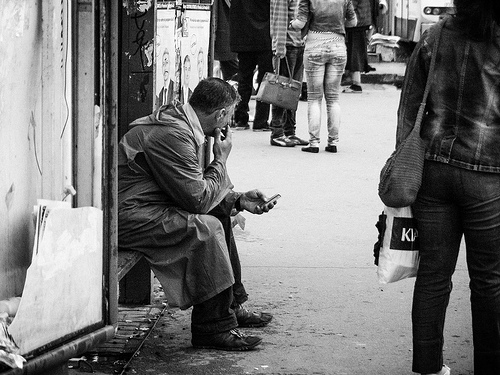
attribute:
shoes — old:
[200, 301, 275, 354]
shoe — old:
[238, 304, 275, 328]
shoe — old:
[188, 326, 264, 348]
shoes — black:
[191, 307, 278, 357]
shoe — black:
[229, 307, 275, 325]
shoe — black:
[195, 327, 267, 354]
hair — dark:
[188, 75, 238, 117]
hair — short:
[187, 75, 241, 115]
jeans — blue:
[300, 28, 351, 149]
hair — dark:
[443, 0, 499, 84]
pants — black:
[391, 163, 496, 334]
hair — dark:
[439, 8, 499, 145]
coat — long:
[118, 126, 234, 324]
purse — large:
[259, 73, 303, 123]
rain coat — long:
[120, 101, 243, 307]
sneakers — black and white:
[270, 135, 307, 147]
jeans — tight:
[384, 170, 484, 347]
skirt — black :
[350, 12, 375, 70]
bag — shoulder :
[380, 52, 435, 199]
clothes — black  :
[212, 23, 262, 56]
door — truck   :
[157, 8, 185, 115]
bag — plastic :
[372, 37, 434, 209]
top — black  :
[294, 1, 359, 38]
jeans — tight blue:
[381, 11, 481, 372]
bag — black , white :
[373, 198, 427, 286]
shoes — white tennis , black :
[199, 300, 279, 349]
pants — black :
[392, 172, 483, 358]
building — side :
[4, 5, 241, 365]